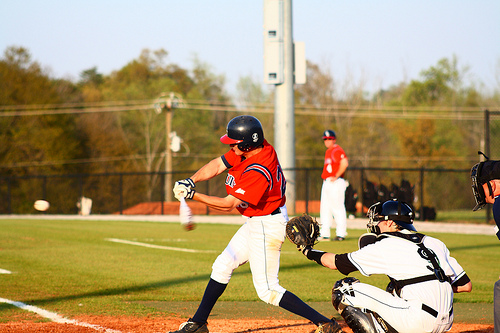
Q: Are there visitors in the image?
A: No, there are no visitors.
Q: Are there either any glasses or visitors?
A: No, there are no visitors or glasses.